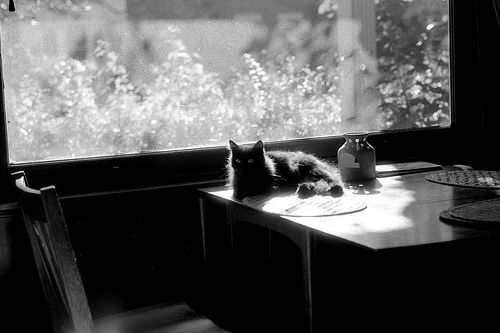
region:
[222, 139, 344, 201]
The cat is lying down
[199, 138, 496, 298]
The cat is on the table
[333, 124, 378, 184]
The jar is on top of the table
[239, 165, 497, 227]
There are three place mats on the table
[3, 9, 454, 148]
There are bushes outside the window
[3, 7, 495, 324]
The table is next to the window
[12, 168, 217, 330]
The chair is made of wood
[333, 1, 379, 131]
A pole outside the window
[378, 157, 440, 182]
A stack of papers on the table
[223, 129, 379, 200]
The cat is next to the jar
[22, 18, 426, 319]
a black and white picture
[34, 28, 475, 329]
picture taken indoors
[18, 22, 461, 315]
picture taken during the day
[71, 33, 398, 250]
the sun is coming in through the window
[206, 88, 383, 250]
a cat on a table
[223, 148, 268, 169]
the cat's eyes are visable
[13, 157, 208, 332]
a chair next to the table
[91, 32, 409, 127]
glass between the cat and the outside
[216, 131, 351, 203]
the cat is laying down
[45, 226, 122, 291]
the chair is made of wood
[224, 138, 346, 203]
A cat on a table.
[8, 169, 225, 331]
A wood dining chair.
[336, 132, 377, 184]
A jar on a table.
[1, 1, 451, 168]
A window above a table.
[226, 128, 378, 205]
A cat and a jar.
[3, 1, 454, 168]
Bushes outside a window.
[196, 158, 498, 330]
A dining room table.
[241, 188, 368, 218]
A place mat on a table.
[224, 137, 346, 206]
A cat by a window.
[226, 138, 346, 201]
A cat laying down.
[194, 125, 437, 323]
a cat is lying on a table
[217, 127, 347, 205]
the cat is black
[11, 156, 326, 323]
a chair is in front a table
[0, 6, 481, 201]
a large window behind a cat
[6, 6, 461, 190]
plants can be seen through the window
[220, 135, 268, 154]
pointy ears of cat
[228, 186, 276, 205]
front legs of cat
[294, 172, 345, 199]
back legs of cat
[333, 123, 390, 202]
a jar on a table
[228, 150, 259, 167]
eyes of cat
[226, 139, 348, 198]
cat sitting on table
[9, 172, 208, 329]
dark wooden chair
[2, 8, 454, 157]
wide window with sun shining in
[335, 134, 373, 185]
jar next to cat on table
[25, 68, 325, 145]
foliage seen through window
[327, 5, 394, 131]
wooden post for porch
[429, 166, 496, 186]
placemat laying on table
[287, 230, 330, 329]
wooden table leg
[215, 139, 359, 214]
furry black cat with rear paws on placemat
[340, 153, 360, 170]
white label on jar